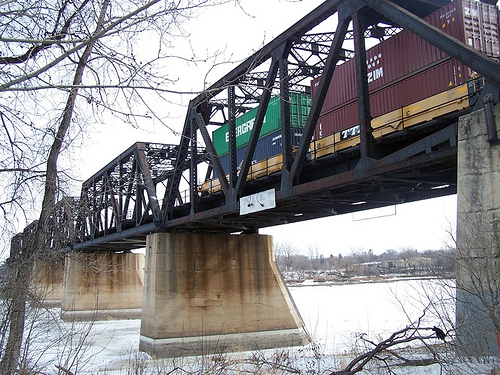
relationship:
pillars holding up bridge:
[458, 135, 496, 270] [102, 72, 264, 236]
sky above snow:
[1, 1, 388, 237] [308, 285, 420, 342]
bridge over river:
[6, 3, 496, 365] [4, 268, 498, 373]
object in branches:
[431, 322, 447, 340] [329, 284, 489, 374]